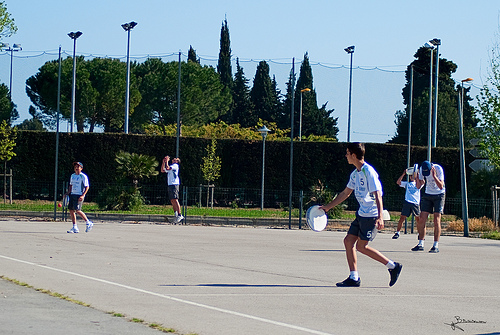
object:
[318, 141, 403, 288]
man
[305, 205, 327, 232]
frisbee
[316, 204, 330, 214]
hand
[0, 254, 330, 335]
line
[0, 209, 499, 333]
playground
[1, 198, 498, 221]
grass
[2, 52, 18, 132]
pole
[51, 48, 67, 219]
pole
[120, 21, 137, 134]
pole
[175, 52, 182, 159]
pole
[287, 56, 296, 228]
pole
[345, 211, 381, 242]
shorts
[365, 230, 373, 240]
number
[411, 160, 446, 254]
man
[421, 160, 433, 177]
cap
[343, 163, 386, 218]
shirt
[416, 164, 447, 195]
shirt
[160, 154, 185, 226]
man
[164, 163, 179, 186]
shirt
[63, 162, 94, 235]
man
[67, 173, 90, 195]
shirt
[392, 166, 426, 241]
man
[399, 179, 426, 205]
shirt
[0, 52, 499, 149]
netting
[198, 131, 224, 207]
trees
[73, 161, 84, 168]
cap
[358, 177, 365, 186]
number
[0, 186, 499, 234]
fence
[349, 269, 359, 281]
socks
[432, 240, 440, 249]
socks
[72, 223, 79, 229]
socks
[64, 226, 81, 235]
shoes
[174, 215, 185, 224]
shoes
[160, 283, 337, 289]
shadow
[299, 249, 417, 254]
shadow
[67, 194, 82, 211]
shorts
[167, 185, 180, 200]
shorts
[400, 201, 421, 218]
shorts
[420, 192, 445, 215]
shorts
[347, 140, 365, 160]
hair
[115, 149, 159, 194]
bush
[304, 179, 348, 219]
bush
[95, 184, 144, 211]
bush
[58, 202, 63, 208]
ball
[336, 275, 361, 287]
sneaker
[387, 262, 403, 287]
sneaker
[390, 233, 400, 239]
sneaker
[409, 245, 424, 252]
sneaker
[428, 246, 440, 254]
sneaker